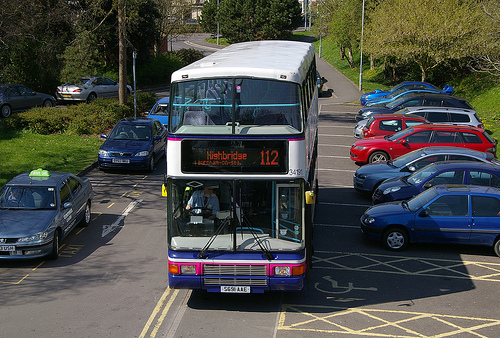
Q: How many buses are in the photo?
A: 1.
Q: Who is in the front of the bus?
A: The bus driver.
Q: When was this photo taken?
A: During the day.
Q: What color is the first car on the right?
A: Blue.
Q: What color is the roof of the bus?
A: White.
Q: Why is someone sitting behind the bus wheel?
A: To drive the bus.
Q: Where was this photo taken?
A: In a parking lot.